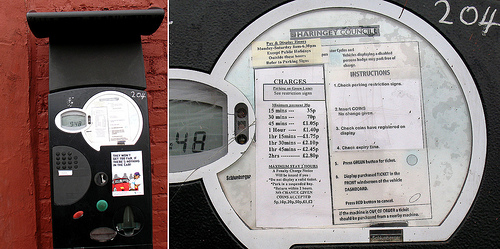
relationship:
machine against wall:
[27, 9, 162, 246] [0, 0, 51, 247]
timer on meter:
[59, 111, 88, 127] [21, 5, 166, 245]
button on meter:
[71, 209, 83, 217] [0, 0, 498, 246]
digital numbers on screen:
[162, 121, 217, 156] [169, 98, 224, 155]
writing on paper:
[267, 162, 317, 169] [254, 37, 431, 226]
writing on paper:
[270, 199, 315, 205] [254, 37, 431, 226]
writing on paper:
[341, 170, 401, 177] [254, 37, 431, 226]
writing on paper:
[332, 80, 404, 90] [254, 37, 431, 226]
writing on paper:
[345, 65, 394, 77] [254, 37, 431, 226]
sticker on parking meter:
[74, 94, 143, 150] [24, 10, 163, 247]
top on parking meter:
[21, 6, 164, 33] [24, 10, 163, 247]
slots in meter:
[81, 197, 167, 242] [15, 6, 409, 246]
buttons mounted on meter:
[54, 150, 79, 169] [44, 82, 167, 227]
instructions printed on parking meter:
[320, 42, 430, 224] [169, 1, 485, 242]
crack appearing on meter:
[166, 117, 258, 204] [170, 7, 248, 187]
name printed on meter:
[288, 25, 378, 38] [6, 12, 336, 238]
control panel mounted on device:
[52, 149, 79, 169] [30, 13, 232, 203]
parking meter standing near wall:
[24, 10, 163, 247] [0, 0, 167, 248]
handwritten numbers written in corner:
[429, 0, 500, 36] [391, 2, 484, 64]